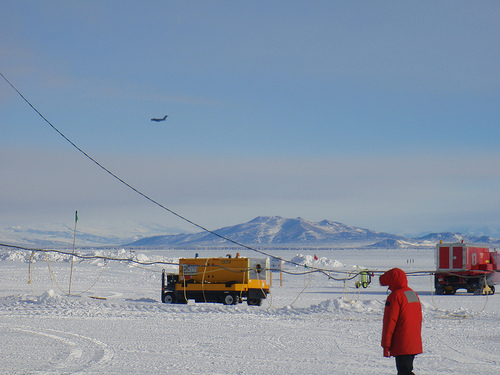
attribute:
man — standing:
[380, 268, 424, 374]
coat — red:
[380, 268, 427, 356]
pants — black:
[392, 355, 418, 374]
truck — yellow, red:
[161, 254, 273, 306]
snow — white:
[2, 244, 499, 372]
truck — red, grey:
[432, 242, 500, 296]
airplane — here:
[150, 115, 169, 125]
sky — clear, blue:
[0, 1, 498, 233]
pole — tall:
[68, 211, 79, 296]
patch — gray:
[406, 292, 418, 303]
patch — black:
[384, 302, 392, 306]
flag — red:
[313, 255, 318, 261]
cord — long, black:
[0, 72, 439, 277]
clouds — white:
[0, 147, 498, 210]